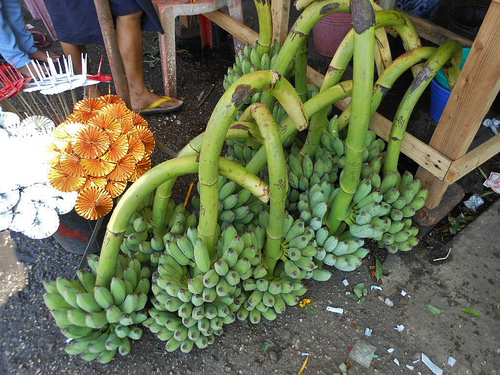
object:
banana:
[190, 235, 214, 273]